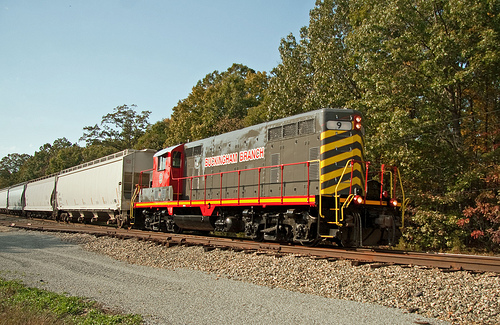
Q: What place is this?
A: It is a road.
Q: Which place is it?
A: It is a road.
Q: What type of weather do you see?
A: It is clear.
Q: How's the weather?
A: It is clear.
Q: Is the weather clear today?
A: Yes, it is clear.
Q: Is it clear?
A: Yes, it is clear.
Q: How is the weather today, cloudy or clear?
A: It is clear.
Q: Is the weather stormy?
A: No, it is clear.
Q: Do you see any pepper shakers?
A: No, there are no pepper shakers.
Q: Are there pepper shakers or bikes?
A: No, there are no pepper shakers or bikes.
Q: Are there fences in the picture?
A: No, there are no fences.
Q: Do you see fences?
A: No, there are no fences.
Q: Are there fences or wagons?
A: No, there are no fences or wagons.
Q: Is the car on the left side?
A: Yes, the car is on the left of the image.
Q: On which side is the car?
A: The car is on the left of the image.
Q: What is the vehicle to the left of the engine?
A: The vehicle is a car.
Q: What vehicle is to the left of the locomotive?
A: The vehicle is a car.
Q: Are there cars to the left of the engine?
A: Yes, there is a car to the left of the engine.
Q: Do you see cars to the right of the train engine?
A: No, the car is to the left of the train engine.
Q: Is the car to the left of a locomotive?
A: Yes, the car is to the left of a locomotive.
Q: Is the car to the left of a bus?
A: No, the car is to the left of a locomotive.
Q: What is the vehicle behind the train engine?
A: The vehicle is a car.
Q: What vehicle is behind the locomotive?
A: The vehicle is a car.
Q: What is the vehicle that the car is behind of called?
A: The vehicle is a locomotive.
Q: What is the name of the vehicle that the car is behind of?
A: The vehicle is a locomotive.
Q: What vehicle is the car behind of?
A: The car is behind the engine.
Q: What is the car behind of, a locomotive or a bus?
A: The car is behind a locomotive.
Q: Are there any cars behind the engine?
A: Yes, there is a car behind the engine.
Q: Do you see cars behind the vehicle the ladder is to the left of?
A: Yes, there is a car behind the engine.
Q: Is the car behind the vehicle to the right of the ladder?
A: Yes, the car is behind the engine.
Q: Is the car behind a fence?
A: No, the car is behind the engine.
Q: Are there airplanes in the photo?
A: No, there are no airplanes.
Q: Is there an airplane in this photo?
A: No, there are no airplanes.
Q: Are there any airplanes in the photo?
A: No, there are no airplanes.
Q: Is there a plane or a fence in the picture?
A: No, there are no airplanes or fences.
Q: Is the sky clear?
A: Yes, the sky is clear.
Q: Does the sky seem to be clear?
A: Yes, the sky is clear.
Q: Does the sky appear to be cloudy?
A: No, the sky is clear.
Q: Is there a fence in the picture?
A: No, there are no fences.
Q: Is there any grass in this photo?
A: Yes, there is grass.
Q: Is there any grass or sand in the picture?
A: Yes, there is grass.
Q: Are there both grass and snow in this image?
A: No, there is grass but no snow.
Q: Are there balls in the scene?
A: No, there are no balls.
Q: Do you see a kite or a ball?
A: No, there are no balls or kites.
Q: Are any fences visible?
A: No, there are no fences.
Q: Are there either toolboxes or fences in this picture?
A: No, there are no fences or toolboxes.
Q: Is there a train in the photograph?
A: Yes, there is a train.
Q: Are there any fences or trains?
A: Yes, there is a train.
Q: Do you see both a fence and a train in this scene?
A: No, there is a train but no fences.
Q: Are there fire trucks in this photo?
A: No, there are no fire trucks.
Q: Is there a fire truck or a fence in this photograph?
A: No, there are no fire trucks or fences.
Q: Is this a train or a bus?
A: This is a train.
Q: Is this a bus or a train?
A: This is a train.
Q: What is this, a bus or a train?
A: This is a train.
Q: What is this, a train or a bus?
A: This is a train.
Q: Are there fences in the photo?
A: No, there are no fences.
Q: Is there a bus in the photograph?
A: No, there are no buses.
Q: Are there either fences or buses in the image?
A: No, there are no buses or fences.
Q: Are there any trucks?
A: No, there are no trucks.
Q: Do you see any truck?
A: No, there are no trucks.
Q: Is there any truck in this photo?
A: No, there are no trucks.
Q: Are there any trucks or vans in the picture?
A: No, there are no trucks or vans.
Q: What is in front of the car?
A: The train engine is in front of the car.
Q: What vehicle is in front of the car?
A: The vehicle is a locomotive.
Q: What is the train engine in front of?
A: The train engine is in front of the car.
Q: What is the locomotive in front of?
A: The train engine is in front of the car.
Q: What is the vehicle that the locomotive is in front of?
A: The vehicle is a car.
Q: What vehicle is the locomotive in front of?
A: The locomotive is in front of the car.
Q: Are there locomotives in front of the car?
A: Yes, there is a locomotive in front of the car.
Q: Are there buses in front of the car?
A: No, there is a locomotive in front of the car.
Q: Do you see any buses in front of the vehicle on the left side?
A: No, there is a locomotive in front of the car.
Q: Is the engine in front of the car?
A: Yes, the engine is in front of the car.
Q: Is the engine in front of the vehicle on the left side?
A: Yes, the engine is in front of the car.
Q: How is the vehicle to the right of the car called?
A: The vehicle is a locomotive.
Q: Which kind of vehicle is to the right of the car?
A: The vehicle is a locomotive.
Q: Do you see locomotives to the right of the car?
A: Yes, there is a locomotive to the right of the car.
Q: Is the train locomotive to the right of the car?
A: Yes, the locomotive is to the right of the car.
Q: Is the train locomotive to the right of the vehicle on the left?
A: Yes, the locomotive is to the right of the car.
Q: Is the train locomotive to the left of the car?
A: No, the engine is to the right of the car.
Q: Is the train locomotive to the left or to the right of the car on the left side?
A: The engine is to the right of the car.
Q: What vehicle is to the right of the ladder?
A: The vehicle is a locomotive.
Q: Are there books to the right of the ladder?
A: No, there is a locomotive to the right of the ladder.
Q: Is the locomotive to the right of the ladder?
A: Yes, the locomotive is to the right of the ladder.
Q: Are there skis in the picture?
A: No, there are no skis.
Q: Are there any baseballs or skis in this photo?
A: No, there are no skis or baseballs.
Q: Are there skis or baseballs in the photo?
A: No, there are no skis or baseballs.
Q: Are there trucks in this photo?
A: No, there are no trucks.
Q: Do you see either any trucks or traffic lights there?
A: No, there are no trucks or traffic lights.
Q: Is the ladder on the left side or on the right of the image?
A: The ladder is on the left of the image.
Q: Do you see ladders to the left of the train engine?
A: Yes, there is a ladder to the left of the train engine.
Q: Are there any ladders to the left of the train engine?
A: Yes, there is a ladder to the left of the train engine.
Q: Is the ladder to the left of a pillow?
A: No, the ladder is to the left of the locomotive.